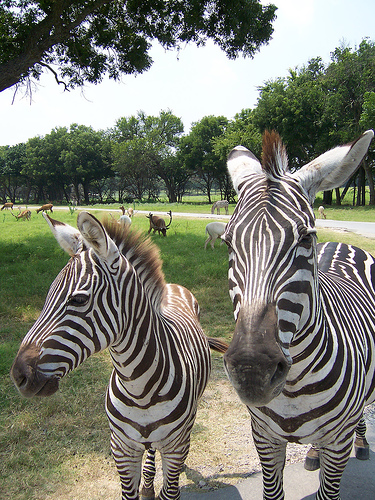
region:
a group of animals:
[6, 120, 373, 490]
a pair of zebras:
[9, 94, 374, 492]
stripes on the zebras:
[10, 126, 371, 497]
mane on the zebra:
[93, 218, 183, 302]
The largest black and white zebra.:
[217, 129, 373, 498]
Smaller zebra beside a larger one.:
[9, 210, 210, 498]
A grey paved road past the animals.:
[1, 203, 374, 237]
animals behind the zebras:
[3, 181, 258, 363]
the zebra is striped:
[2, 182, 216, 497]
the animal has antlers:
[142, 204, 182, 241]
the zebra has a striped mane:
[86, 212, 192, 340]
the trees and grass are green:
[3, 110, 241, 299]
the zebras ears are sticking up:
[30, 201, 132, 289]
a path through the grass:
[8, 193, 371, 256]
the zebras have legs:
[91, 377, 372, 498]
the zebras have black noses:
[2, 327, 303, 420]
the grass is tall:
[6, 208, 235, 307]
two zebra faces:
[36, 201, 354, 417]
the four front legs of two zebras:
[97, 420, 357, 498]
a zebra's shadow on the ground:
[174, 458, 247, 498]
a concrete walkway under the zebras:
[240, 482, 255, 498]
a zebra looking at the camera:
[215, 137, 371, 493]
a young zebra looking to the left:
[30, 234, 191, 494]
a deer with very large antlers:
[133, 205, 181, 238]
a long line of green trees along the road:
[9, 106, 372, 182]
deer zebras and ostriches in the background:
[1, 197, 251, 238]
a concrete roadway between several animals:
[104, 202, 230, 218]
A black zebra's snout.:
[209, 308, 310, 416]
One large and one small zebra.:
[22, 215, 357, 493]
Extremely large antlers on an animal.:
[140, 209, 179, 232]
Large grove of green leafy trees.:
[2, 77, 367, 212]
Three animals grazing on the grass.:
[0, 198, 68, 225]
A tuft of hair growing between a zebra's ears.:
[260, 122, 297, 179]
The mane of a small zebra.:
[94, 209, 171, 302]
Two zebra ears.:
[36, 203, 123, 260]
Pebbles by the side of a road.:
[189, 438, 252, 489]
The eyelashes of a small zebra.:
[68, 292, 87, 302]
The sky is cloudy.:
[289, 2, 347, 36]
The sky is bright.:
[284, 0, 361, 34]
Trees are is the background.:
[31, 117, 189, 200]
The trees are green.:
[42, 133, 185, 189]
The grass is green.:
[165, 235, 201, 273]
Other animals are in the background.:
[2, 195, 251, 257]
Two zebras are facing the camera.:
[9, 138, 373, 498]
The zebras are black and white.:
[7, 136, 369, 493]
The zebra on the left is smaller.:
[3, 208, 213, 496]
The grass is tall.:
[170, 240, 202, 271]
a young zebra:
[11, 209, 219, 498]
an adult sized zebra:
[223, 128, 373, 498]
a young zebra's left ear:
[76, 208, 124, 261]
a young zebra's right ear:
[46, 212, 86, 252]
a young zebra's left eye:
[68, 291, 91, 308]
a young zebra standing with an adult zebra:
[12, 130, 373, 498]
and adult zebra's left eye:
[295, 225, 314, 252]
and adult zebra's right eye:
[221, 233, 238, 251]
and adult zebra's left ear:
[301, 128, 373, 194]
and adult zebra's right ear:
[226, 143, 264, 183]